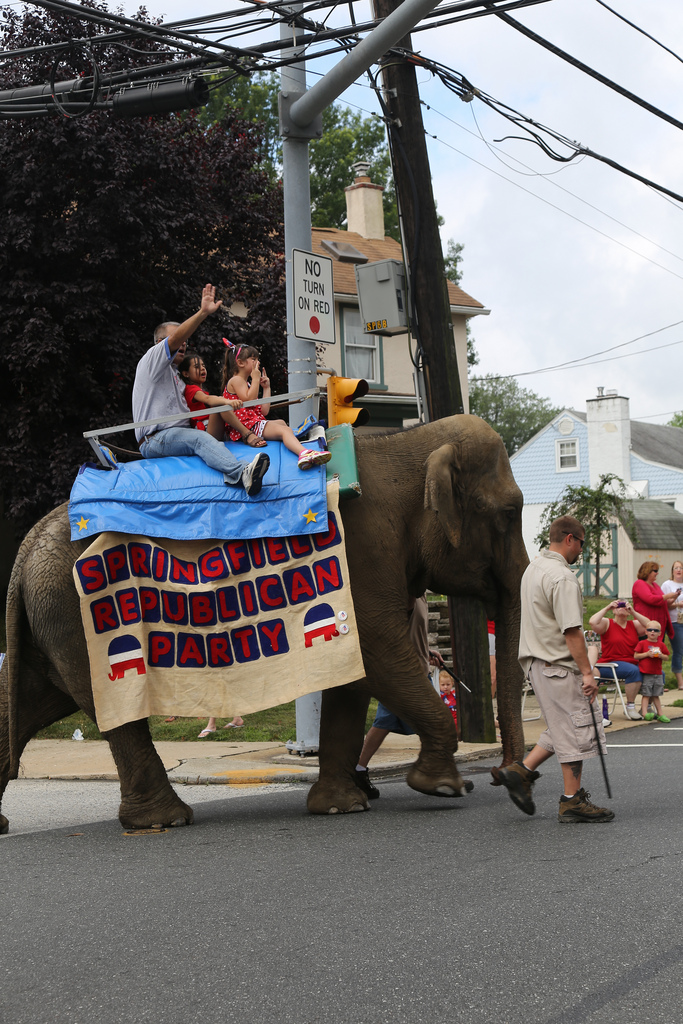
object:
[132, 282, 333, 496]
man/two kids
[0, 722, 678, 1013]
street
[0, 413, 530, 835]
elephant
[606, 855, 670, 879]
crack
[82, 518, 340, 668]
writing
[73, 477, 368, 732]
item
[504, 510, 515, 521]
eye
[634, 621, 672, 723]
people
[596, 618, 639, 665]
clothing